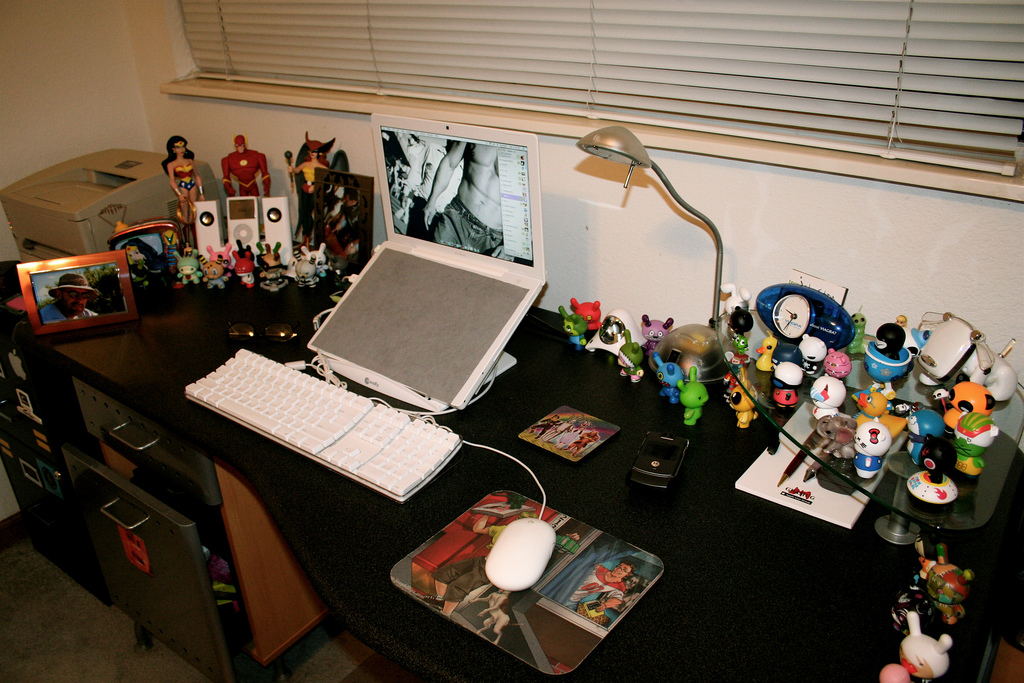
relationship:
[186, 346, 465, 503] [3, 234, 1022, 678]
keyboard on desk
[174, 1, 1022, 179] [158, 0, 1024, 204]
blinds cover blinds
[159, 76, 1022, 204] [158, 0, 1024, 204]
ledge of blinds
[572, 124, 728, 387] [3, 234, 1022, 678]
lamp on desk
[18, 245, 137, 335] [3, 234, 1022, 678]
frame on desk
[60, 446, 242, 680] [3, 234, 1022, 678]
drawer on desk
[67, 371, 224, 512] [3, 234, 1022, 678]
drawer on desk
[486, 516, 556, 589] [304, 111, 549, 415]
mouse on computer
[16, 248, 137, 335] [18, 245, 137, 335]
frame inside frame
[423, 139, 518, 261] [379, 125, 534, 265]
man on screen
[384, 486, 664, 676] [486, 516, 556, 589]
mousepad used to help mouse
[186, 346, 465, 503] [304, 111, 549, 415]
keyboard for a computer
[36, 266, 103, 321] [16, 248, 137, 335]
man in frame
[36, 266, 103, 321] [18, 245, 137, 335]
man in a frame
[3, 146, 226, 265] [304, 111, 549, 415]
printer used for computer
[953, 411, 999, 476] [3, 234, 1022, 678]
action figure sitting on desk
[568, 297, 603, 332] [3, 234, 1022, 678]
action figure sitting on desk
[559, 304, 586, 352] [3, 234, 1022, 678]
action figure sitting on desk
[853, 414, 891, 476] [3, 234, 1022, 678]
action figure sitting on desk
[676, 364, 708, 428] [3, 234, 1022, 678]
action figure sitting on desk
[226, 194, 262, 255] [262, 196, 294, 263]
ipod on speaker